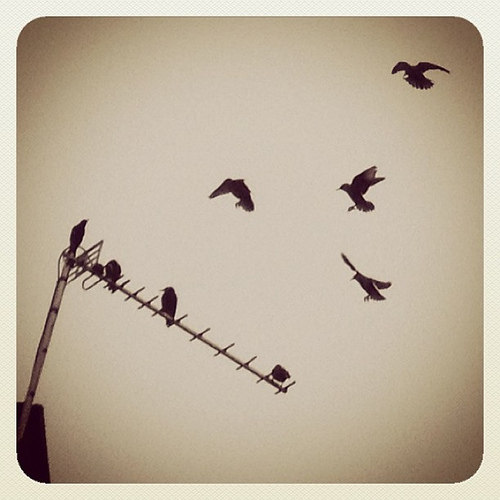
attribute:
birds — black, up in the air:
[67, 61, 450, 385]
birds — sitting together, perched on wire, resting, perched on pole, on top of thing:
[67, 218, 292, 386]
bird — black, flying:
[391, 58, 450, 94]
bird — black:
[158, 285, 182, 331]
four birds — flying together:
[205, 59, 451, 312]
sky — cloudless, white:
[16, 14, 484, 485]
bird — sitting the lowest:
[268, 361, 296, 387]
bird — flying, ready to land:
[209, 175, 257, 216]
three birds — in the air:
[330, 57, 455, 304]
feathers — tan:
[333, 171, 389, 216]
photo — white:
[26, 6, 488, 479]